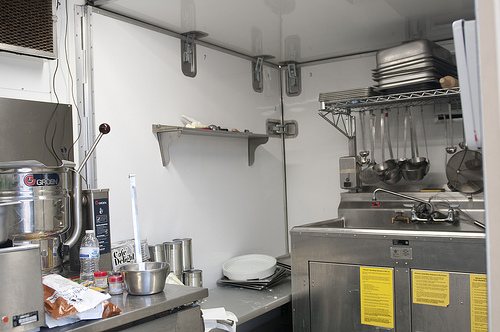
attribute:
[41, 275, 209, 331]
counter — stainless steel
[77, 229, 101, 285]
bottle — disposable, plastic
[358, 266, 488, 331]
signs — yellow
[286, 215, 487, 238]
sink — stainless steel, large, silver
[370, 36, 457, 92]
pans — stacked, stainless steel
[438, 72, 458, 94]
rolling pin — wooden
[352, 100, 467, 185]
ladles — hanging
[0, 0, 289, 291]
wall — white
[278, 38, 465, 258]
wall — white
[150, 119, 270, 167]
shelf — metal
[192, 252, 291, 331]
counter — stainless steel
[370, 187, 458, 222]
faucet — stainless steel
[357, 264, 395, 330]
sign — yellow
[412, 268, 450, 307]
sign — yellow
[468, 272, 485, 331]
sign — yellow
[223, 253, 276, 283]
cake pan — white